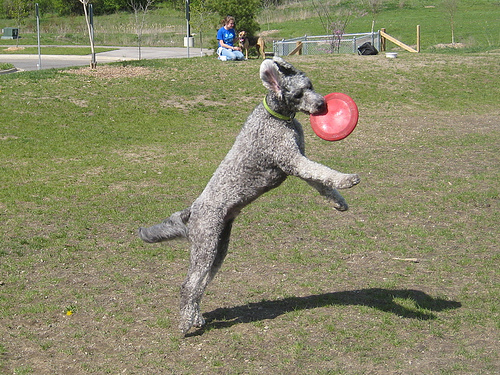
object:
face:
[282, 75, 326, 114]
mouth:
[300, 89, 325, 114]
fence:
[271, 24, 420, 56]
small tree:
[310, 0, 357, 53]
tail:
[138, 207, 192, 244]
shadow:
[184, 288, 462, 338]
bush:
[202, 0, 264, 57]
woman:
[216, 16, 244, 61]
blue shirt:
[217, 26, 235, 49]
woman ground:
[199, 12, 254, 67]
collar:
[263, 95, 292, 120]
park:
[1, 3, 499, 373]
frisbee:
[310, 92, 359, 141]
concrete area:
[23, 298, 110, 360]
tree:
[119, 0, 154, 58]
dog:
[138, 57, 359, 339]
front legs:
[274, 139, 340, 189]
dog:
[238, 31, 267, 60]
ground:
[206, 59, 262, 71]